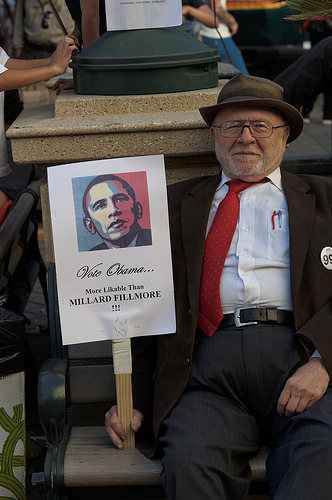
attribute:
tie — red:
[200, 179, 260, 330]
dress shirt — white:
[213, 172, 290, 312]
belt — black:
[204, 305, 294, 330]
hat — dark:
[198, 71, 309, 117]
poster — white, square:
[38, 154, 179, 345]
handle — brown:
[113, 374, 137, 447]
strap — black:
[43, 0, 67, 37]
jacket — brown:
[153, 174, 324, 400]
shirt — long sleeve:
[14, 1, 72, 44]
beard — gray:
[214, 136, 286, 181]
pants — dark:
[166, 327, 329, 498]